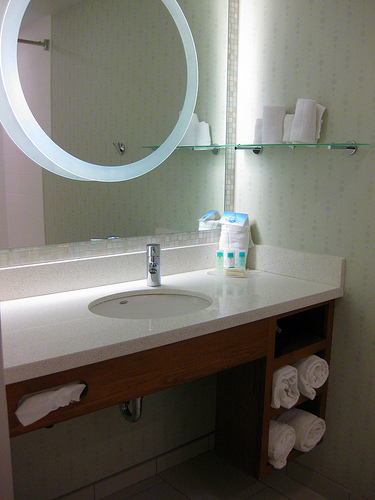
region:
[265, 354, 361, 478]
four towels under the sink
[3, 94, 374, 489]
sink at a hotel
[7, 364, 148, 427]
box of tissue in the cabinet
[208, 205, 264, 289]
complimentary shampoo, conditioner, lotion and soap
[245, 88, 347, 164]
wash cloths and hand towels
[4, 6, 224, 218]
circle design on the mirror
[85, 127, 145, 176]
hook to hang towel on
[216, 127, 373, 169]
glass shelf in bathroom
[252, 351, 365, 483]
four rolled up towels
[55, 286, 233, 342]
sink in the bathroom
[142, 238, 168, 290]
a silver sink faucet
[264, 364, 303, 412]
a rolled white towel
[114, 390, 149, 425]
a silver pipe under the sink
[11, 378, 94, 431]
a tissue dispenser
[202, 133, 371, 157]
a glass shelf on the wall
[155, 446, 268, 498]
a tile on the floor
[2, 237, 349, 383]
a white bathroom counter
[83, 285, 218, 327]
a white sink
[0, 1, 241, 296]
a mirror on the wall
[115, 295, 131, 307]
a hole in the sink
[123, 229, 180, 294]
gray faucet on counter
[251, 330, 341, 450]
towels under sink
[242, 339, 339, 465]
towels put into compartments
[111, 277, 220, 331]
sink on counter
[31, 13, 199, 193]
round mirror on the wall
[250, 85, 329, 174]
towels next to sink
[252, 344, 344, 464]
four towels in compartments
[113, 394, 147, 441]
silver pipe under sink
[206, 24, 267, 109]
light hanging from ceiling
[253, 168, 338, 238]
white wall next to counter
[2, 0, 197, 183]
the mirror's casing is white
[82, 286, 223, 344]
the sink faucet has no knobs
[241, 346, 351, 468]
towels are in the shelf of the sink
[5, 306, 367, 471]
the shelf is brown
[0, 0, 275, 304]
lights are around the mirror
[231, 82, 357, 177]
the shelf is made of glass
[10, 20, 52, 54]
the rod to hold shower curtain is displayed in mirror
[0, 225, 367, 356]
the countertop is white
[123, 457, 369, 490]
the floor is tiled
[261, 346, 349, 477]
the towels are white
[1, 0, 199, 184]
The circular mirror on the larger mirror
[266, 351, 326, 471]
The four rolled towels in the cubbies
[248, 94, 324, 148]
The towels on the shelf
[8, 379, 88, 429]
The tissues in the counter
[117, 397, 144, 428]
The pipes under the sink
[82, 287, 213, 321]
The circular sink basin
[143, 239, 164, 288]
The sink faucet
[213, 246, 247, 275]
The three bottles on the counter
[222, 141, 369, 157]
The glass shelf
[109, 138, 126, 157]
The hook on the wall